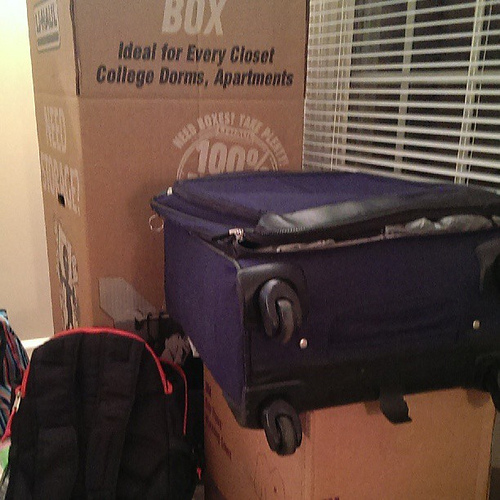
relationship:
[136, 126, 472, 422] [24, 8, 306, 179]
suitcase on box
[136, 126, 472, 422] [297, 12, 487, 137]
suitcase in front of blind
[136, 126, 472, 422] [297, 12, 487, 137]
suitcase in front of window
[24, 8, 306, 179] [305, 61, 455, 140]
box in window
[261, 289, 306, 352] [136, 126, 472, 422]
wheel of suitcase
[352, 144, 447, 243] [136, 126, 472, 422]
piece of luggage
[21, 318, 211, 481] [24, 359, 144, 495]
backpack has straps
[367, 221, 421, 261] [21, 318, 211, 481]
zipper of backpack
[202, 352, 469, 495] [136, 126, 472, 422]
bottom of suitcase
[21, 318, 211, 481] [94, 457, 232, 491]
bag on floor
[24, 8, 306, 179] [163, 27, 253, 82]
box in text